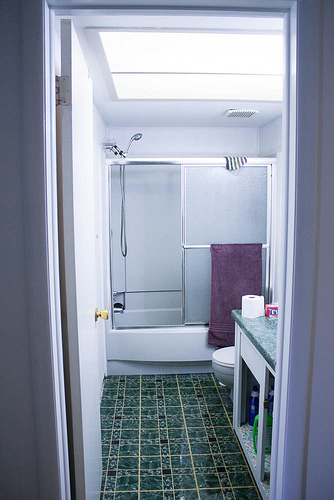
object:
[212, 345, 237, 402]
toilet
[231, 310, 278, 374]
countertop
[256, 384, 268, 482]
items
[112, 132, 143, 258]
shower attachment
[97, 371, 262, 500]
floor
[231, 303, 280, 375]
counter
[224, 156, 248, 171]
wash cloth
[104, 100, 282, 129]
ceiling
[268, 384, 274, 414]
product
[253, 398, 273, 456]
green bottle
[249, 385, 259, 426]
cleaning supply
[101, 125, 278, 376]
shower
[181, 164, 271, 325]
door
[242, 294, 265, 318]
toilet paper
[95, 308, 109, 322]
handle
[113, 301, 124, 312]
nozzel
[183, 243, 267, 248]
rack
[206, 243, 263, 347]
towel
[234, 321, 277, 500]
cabinet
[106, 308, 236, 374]
bathtub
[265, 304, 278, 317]
box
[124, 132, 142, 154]
shower head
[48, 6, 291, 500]
bathroom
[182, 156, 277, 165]
rod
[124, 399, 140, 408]
tile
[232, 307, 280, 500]
sink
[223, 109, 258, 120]
vent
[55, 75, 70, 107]
bracket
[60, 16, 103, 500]
door